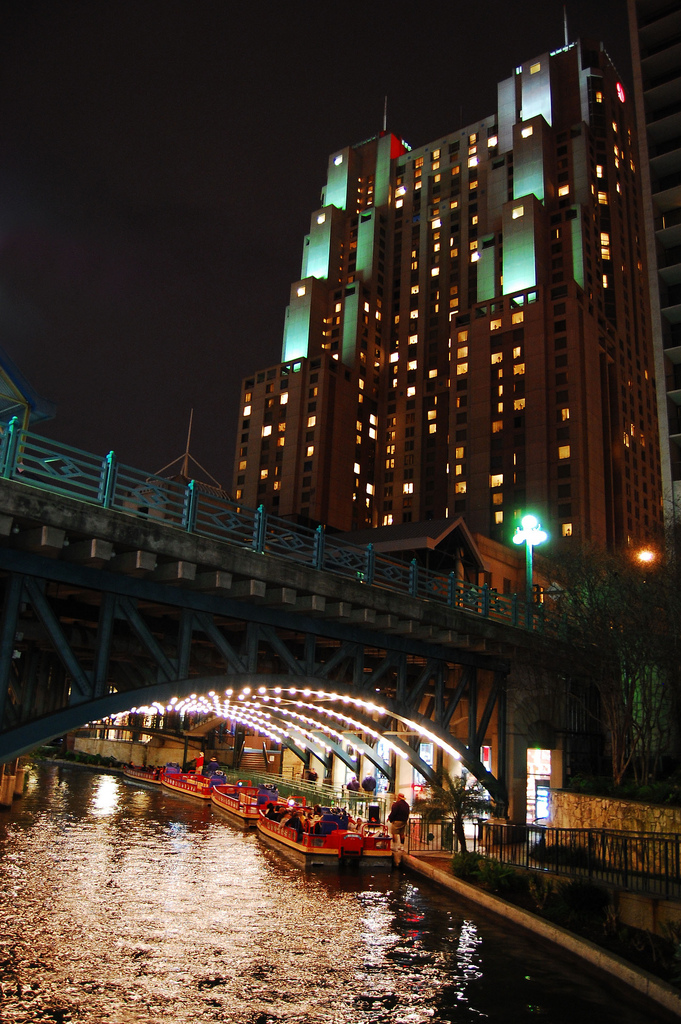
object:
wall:
[541, 785, 680, 887]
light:
[509, 510, 549, 605]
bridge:
[1, 411, 632, 832]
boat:
[208, 777, 274, 831]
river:
[2, 743, 677, 1019]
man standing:
[386, 792, 411, 853]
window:
[490, 317, 502, 331]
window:
[510, 307, 524, 325]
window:
[512, 346, 522, 359]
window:
[490, 348, 504, 365]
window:
[512, 362, 526, 375]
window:
[455, 346, 468, 358]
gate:
[403, 811, 679, 899]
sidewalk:
[418, 838, 679, 995]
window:
[551, 332, 574, 352]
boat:
[255, 783, 399, 876]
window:
[456, 329, 467, 342]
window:
[513, 399, 525, 413]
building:
[236, 39, 678, 639]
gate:
[1, 414, 572, 635]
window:
[442, 252, 498, 296]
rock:
[643, 807, 663, 826]